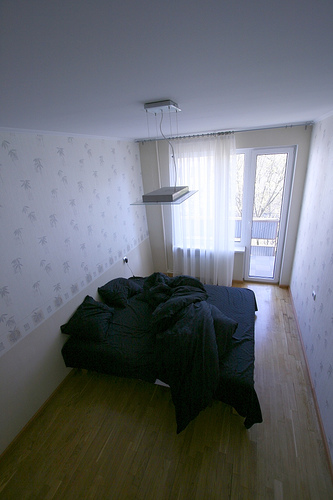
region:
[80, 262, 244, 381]
the bed is black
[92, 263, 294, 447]
the bed is unmade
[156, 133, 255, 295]
the curtain is white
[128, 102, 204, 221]
a lamp hanging from the ceiling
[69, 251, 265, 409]
bed in bedroom on wood floor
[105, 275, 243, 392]
black bed spread on the bed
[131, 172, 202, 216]
cable box up on a shelf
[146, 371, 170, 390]
white part of bed under the sheet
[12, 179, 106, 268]
tropical wall paper on the wall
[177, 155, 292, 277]
back window on the building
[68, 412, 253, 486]
hardwood floor in the bedroom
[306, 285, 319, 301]
electrical outlet on the wall of room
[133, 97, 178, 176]
lots of wires hanging from the ceiling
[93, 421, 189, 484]
hardwood floor in the bed room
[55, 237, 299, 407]
FUTON IN ROOM WITH BLACK COMFORTER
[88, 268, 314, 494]
WOODEN FLOORS IN BEDROOM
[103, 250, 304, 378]
THICK BLACK COMFORTER ON BED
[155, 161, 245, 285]
WHITE CURTAINS OVER WINDOW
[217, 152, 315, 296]
GLASS DOOR ON FAR WALL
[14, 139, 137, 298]
WALL PAPER ON WALLS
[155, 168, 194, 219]
DEVICE ON PLATFORM HANGING FROM CEILING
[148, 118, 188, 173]
WHITE WIRE COMING FROM CEILING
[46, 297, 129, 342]
BLACK PILLOW ON BED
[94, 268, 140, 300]
BLACK PILLOW ON BED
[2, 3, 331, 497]
a bedroom in an apartment unit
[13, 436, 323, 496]
hardwood floors in the bedroom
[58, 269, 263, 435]
a king size bed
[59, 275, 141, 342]
two pillows on the head of the bed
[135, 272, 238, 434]
a black comforter on top of the bed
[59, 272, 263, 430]
black linen on the bed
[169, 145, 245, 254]
a window in the bedroom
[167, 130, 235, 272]
a white sheer curtain covering the window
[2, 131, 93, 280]
wall paper on the walls in the bedroom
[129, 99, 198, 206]
a light fixture on the ceiling